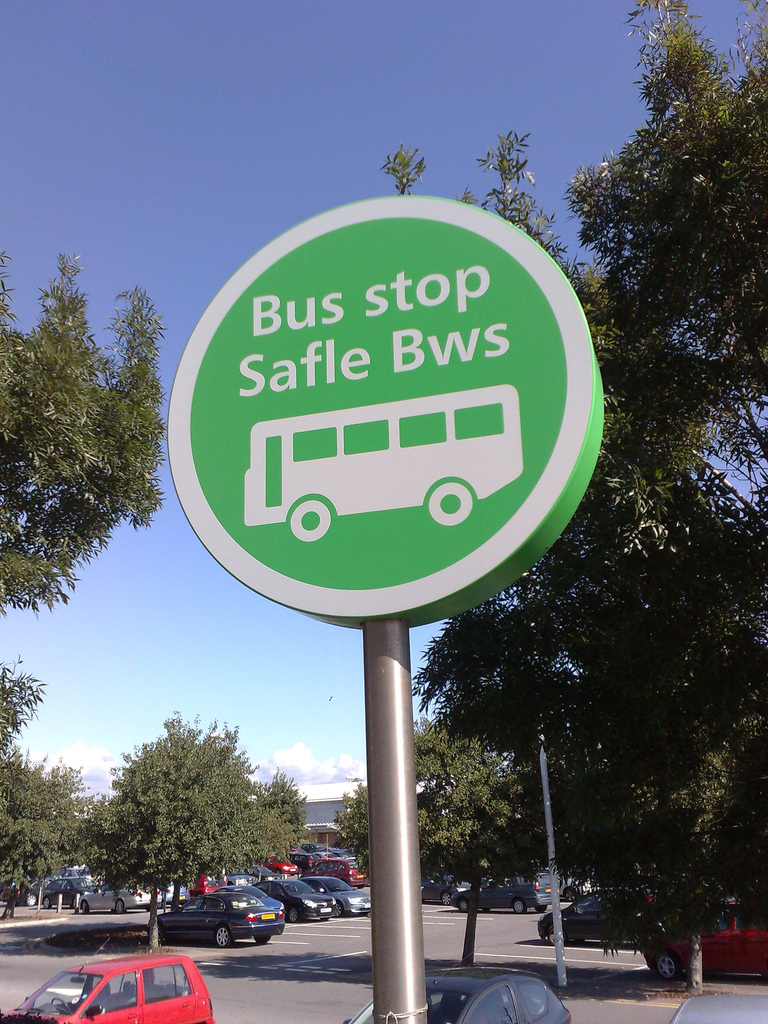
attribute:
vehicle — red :
[2, 949, 220, 1022]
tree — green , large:
[358, 687, 562, 990]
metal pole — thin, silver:
[361, 618, 431, 1022]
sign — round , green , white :
[165, 192, 606, 625]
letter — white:
[249, 294, 280, 338]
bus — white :
[211, 374, 550, 534]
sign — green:
[95, 106, 635, 609]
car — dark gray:
[155, 888, 286, 946]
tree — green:
[83, 712, 296, 948]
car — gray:
[369, 949, 564, 1022]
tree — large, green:
[79, 715, 312, 950]